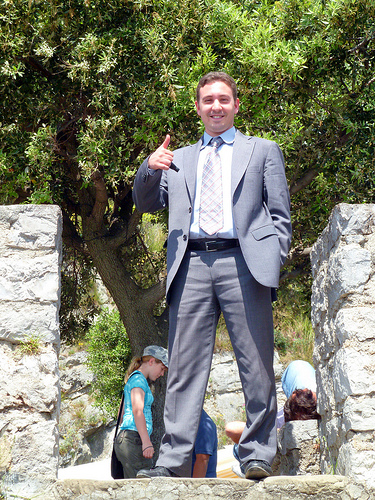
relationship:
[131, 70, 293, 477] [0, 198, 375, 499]
man on rock wall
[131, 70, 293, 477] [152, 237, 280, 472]
man wearing pants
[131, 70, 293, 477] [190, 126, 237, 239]
man wearing shirt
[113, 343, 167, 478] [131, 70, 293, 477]
girl behind man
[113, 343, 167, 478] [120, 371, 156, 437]
girl wearing shirt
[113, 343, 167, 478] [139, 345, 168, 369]
girl wearing hat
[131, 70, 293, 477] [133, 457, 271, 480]
man wearing shoes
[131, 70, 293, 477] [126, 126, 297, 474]
man in a suit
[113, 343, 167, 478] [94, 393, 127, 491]
girl carrying purse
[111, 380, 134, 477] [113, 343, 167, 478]
bag worn by girl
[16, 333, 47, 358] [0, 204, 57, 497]
plant growing in wall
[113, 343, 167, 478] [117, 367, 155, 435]
girl wearing shirt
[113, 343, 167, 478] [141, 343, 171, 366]
girl wearing cap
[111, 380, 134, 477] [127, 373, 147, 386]
bag hanging from shoulder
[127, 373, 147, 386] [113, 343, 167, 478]
shoulder of girl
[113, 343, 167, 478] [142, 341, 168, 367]
girl in hat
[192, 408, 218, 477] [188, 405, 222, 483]
person wears blue t-shirt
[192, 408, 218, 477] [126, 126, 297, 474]
person wears suit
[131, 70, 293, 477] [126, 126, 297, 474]
man wears suit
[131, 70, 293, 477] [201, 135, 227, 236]
man wears tie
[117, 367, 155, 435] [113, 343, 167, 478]
shirt worn by girl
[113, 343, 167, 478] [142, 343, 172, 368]
girl in a hat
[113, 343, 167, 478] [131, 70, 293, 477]
girl standing behind man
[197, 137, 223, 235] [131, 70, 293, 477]
tie on man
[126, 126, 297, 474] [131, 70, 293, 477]
suit on man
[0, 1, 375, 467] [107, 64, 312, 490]
tree behind man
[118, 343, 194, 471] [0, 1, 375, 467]
girl leaning on tree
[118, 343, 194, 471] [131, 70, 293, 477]
girl behind man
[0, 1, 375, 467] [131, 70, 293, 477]
tree behind man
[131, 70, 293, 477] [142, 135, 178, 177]
man giving thumbs up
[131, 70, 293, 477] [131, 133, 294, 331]
man in grey suit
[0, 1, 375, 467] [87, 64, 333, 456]
tree behind people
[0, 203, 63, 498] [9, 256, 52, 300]
wall made of stones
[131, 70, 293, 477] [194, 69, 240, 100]
man with short hair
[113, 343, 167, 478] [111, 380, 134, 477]
girl carrying bag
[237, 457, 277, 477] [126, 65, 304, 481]
shoe worn by man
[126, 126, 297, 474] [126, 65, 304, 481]
suit worn by man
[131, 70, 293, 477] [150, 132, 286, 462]
man wearing suit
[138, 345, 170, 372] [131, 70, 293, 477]
hat behind man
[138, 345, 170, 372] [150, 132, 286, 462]
hat behind suit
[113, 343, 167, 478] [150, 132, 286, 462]
girl behind suit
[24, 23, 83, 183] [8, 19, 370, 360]
rope in tree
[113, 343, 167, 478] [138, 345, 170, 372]
girl with hat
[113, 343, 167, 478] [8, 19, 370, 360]
girl in front of tree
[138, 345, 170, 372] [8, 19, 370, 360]
hat in front of tree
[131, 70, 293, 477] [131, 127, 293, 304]
man wearing jacket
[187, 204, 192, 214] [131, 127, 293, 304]
button on jacket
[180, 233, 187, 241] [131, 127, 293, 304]
button on jacket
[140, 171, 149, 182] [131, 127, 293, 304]
button on jacket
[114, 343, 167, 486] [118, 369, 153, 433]
person in shirt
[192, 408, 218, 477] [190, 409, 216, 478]
person in shirt